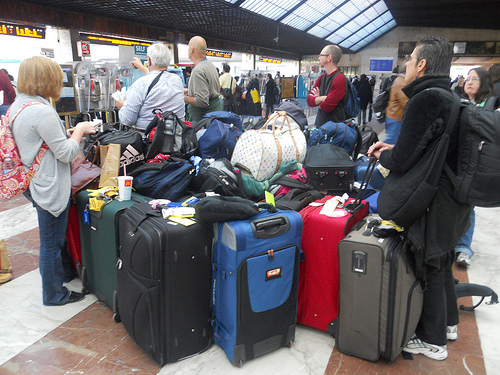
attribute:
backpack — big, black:
[427, 88, 497, 210]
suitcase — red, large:
[295, 191, 370, 341]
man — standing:
[368, 37, 478, 366]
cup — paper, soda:
[116, 173, 134, 202]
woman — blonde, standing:
[7, 55, 100, 309]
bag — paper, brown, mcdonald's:
[96, 142, 122, 195]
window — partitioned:
[226, 1, 401, 55]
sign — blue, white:
[367, 56, 395, 73]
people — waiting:
[8, 29, 500, 362]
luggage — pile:
[67, 99, 429, 366]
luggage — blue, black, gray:
[214, 201, 301, 367]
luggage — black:
[113, 201, 214, 365]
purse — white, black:
[230, 110, 309, 182]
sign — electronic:
[0, 20, 50, 40]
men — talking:
[113, 34, 222, 135]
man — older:
[181, 34, 223, 120]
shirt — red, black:
[305, 69, 353, 128]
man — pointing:
[115, 37, 188, 130]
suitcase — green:
[73, 184, 159, 324]